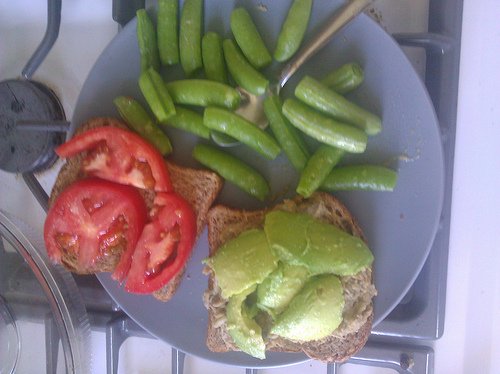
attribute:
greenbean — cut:
[203, 105, 281, 159]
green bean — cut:
[181, 131, 274, 211]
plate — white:
[46, 0, 450, 367]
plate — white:
[376, 91, 416, 125]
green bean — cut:
[181, 2, 205, 72]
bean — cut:
[124, 9, 166, 75]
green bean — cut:
[136, 62, 176, 119]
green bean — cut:
[293, 73, 382, 133]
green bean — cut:
[192, 141, 270, 199]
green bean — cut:
[279, 97, 369, 156]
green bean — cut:
[138, 62, 178, 123]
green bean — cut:
[229, 2, 271, 69]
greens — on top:
[278, 71, 386, 156]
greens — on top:
[136, 61, 248, 141]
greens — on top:
[192, 101, 281, 201]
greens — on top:
[129, 0, 206, 82]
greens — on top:
[222, 1, 314, 65]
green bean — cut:
[220, 36, 270, 96]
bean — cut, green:
[290, 137, 345, 199]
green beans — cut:
[132, 0, 393, 190]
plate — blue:
[54, 35, 440, 352]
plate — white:
[385, 49, 443, 318]